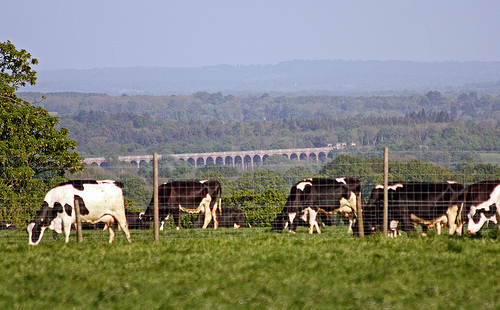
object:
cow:
[136, 179, 223, 231]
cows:
[268, 176, 362, 234]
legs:
[110, 214, 133, 245]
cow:
[27, 179, 134, 245]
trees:
[262, 186, 282, 206]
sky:
[1, 0, 499, 61]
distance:
[1, 0, 498, 98]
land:
[0, 61, 499, 310]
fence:
[0, 161, 499, 241]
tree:
[0, 38, 90, 229]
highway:
[76, 144, 343, 163]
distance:
[27, 92, 500, 167]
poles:
[151, 151, 161, 244]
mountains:
[200, 63, 235, 69]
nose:
[466, 229, 472, 235]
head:
[24, 219, 48, 246]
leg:
[169, 196, 180, 230]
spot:
[63, 203, 71, 217]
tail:
[218, 180, 223, 217]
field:
[1, 226, 500, 310]